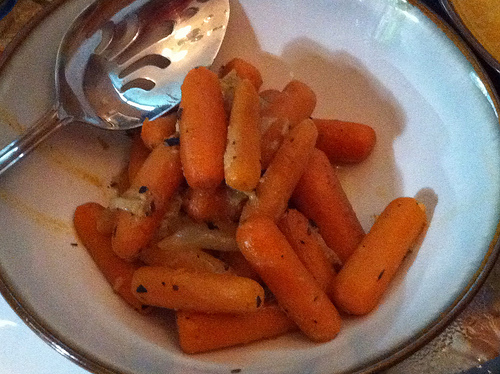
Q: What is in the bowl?
A: Food.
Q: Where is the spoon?
A: In the bowl.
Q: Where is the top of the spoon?
A: On top of the food.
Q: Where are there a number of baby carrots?
A: In a white bowl.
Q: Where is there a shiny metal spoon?
A: In the bowl.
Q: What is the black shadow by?
A: The carrots.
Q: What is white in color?
A: The plate.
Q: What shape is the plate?
A: Round.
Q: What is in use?
A: The plate.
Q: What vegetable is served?
A: Carrot.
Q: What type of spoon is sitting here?
A: Slotted.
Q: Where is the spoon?
A: In a bowl.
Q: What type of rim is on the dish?
A: Brown.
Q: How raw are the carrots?
A: Not at all raw.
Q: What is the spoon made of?
A: Metal.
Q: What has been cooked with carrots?
A: Onions.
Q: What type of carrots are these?
A: Baby.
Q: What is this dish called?
A: Glazed carrots.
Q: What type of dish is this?
A: Stoneware.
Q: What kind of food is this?
A: Cooked carrots.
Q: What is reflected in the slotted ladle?
A: Light from a chandelier.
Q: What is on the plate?
A: A spoon.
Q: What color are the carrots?
A: Orange.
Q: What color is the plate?
A: White.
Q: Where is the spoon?
A: On the left side of the picture.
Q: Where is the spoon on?
A: On the plate.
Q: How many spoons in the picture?
A: One.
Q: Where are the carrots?
A: On the plate.